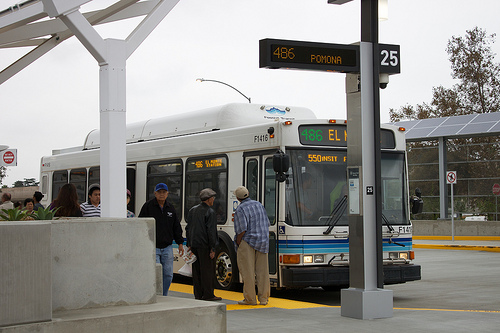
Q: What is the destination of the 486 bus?
A: Pomona.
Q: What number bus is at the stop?
A: 486.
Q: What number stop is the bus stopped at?
A: 25.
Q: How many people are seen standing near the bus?
A: Nine.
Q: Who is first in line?
A: Man in checkered shirt.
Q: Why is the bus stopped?
A: Let people off and on.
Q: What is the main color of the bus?
A: White.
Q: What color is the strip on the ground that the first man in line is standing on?
A: Yellow.